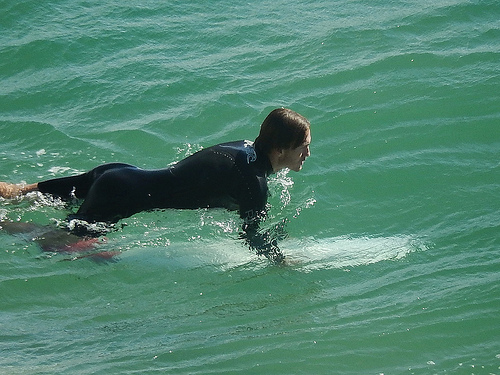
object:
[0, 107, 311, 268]
man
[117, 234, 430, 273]
surfboard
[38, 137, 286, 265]
wetsuit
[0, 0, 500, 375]
ocean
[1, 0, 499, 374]
ripples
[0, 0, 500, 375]
water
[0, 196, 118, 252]
legs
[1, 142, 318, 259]
waves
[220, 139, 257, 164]
design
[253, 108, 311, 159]
hair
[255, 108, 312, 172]
head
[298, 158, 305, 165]
mouth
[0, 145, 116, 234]
foam